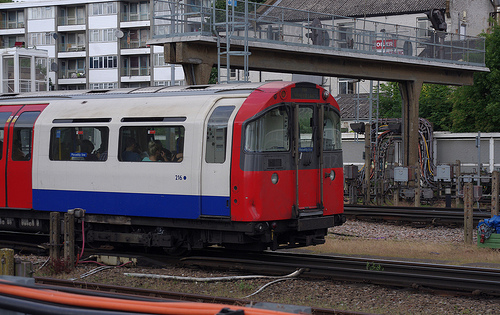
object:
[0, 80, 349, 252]
car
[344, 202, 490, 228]
train tracks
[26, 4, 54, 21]
window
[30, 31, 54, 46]
window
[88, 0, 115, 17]
window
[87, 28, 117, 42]
window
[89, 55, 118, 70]
window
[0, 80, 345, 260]
train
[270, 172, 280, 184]
headlight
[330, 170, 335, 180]
headlight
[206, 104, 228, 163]
window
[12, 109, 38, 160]
window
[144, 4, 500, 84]
walkway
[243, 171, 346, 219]
red paint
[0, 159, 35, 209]
red paint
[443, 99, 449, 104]
leaves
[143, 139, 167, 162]
passengers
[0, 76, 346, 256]
train engine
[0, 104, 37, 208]
door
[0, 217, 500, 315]
ground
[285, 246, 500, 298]
track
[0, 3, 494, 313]
photo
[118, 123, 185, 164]
window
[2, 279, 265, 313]
tubes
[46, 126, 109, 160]
window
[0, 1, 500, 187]
building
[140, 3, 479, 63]
fencing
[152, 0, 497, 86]
balcony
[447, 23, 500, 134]
trees